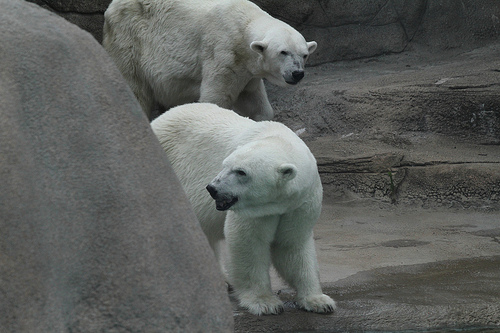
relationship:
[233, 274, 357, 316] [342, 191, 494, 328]
claws on ground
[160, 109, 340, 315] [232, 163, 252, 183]
bear has eyes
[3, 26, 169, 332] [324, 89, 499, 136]
rock has crevices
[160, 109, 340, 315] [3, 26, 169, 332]
bear by rock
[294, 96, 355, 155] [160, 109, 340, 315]
stone by bear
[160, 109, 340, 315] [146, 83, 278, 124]
bear on legs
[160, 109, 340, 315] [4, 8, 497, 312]
bear at zoo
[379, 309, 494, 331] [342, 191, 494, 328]
water on ground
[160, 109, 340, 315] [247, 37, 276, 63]
bear has ears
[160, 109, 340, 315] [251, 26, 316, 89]
bear has head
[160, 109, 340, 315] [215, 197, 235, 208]
bear has teeth